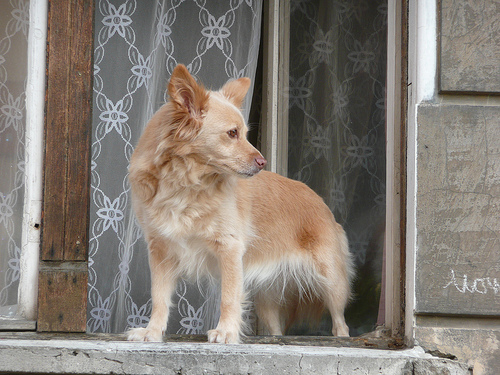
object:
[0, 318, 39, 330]
panel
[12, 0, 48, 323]
pole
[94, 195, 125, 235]
flower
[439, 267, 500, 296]
writing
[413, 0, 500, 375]
wall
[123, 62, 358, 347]
dog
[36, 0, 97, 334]
beam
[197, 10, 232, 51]
flower design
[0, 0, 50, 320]
window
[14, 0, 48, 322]
edging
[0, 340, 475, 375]
cement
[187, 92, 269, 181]
face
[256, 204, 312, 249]
fur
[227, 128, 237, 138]
eye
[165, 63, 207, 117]
ear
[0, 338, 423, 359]
floor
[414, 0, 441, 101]
siding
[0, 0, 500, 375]
building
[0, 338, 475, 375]
ledge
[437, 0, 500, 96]
brick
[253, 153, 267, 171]
nose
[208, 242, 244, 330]
leg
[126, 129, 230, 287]
hair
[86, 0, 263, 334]
curtain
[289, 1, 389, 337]
curtain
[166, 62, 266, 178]
head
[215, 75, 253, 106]
left ear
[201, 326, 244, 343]
paw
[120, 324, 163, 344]
paw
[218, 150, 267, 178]
mouth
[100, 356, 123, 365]
crack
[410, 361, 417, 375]
crack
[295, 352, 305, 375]
crack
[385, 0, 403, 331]
wood